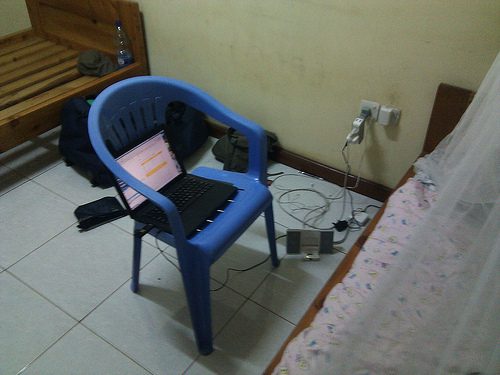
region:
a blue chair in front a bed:
[82, 68, 479, 374]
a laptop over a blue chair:
[87, 78, 251, 268]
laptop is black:
[93, 117, 243, 245]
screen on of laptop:
[93, 125, 193, 215]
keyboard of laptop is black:
[153, 173, 218, 231]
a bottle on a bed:
[0, 6, 159, 97]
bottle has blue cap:
[103, 13, 141, 73]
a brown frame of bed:
[224, 70, 493, 372]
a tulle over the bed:
[327, 98, 496, 373]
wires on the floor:
[267, 119, 367, 263]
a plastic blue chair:
[87, 74, 282, 354]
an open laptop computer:
[109, 128, 236, 239]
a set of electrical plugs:
[348, 95, 380, 148]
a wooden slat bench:
[0, 1, 143, 150]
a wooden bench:
[257, 82, 497, 372]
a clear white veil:
[287, 48, 497, 373]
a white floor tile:
[77, 248, 250, 373]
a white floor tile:
[186, 299, 297, 373]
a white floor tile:
[244, 245, 346, 324]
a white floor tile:
[306, 188, 383, 255]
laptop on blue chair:
[87, 73, 280, 353]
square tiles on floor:
[0, 104, 381, 374]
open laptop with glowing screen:
[112, 128, 233, 235]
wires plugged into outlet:
[272, 97, 379, 224]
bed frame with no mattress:
[0, 0, 150, 154]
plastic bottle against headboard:
[28, 0, 146, 63]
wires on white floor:
[270, 172, 360, 242]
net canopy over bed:
[302, 51, 497, 373]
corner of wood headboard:
[418, 81, 498, 163]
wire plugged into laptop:
[130, 211, 272, 298]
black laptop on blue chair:
[82, 93, 281, 320]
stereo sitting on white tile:
[280, 224, 337, 267]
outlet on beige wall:
[340, 94, 398, 151]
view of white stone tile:
[6, 236, 80, 323]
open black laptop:
[112, 140, 219, 232]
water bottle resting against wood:
[109, 17, 144, 74]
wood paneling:
[11, 43, 56, 102]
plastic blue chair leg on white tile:
[157, 289, 244, 367]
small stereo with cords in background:
[284, 207, 344, 274]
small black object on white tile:
[57, 191, 122, 243]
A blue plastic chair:
[69, 67, 294, 363]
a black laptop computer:
[99, 120, 253, 261]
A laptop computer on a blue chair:
[79, 104, 270, 266]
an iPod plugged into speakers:
[276, 222, 345, 271]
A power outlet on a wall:
[350, 96, 382, 142]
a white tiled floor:
[34, 282, 124, 359]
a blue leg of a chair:
[165, 255, 230, 368]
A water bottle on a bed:
[109, 15, 139, 70]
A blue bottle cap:
[112, 20, 123, 29]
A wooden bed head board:
[0, 0, 150, 82]